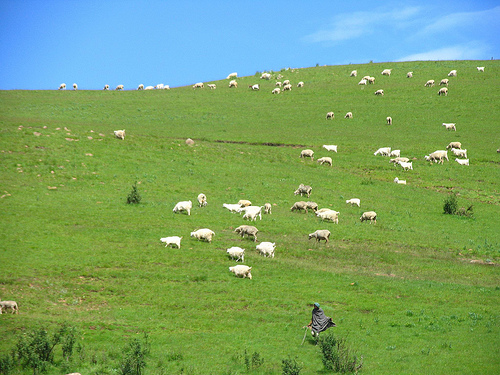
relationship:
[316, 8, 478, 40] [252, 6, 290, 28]
clouds in sky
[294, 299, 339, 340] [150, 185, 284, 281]
person watching sheep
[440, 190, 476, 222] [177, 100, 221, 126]
bush on hill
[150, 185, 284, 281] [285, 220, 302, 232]
sheep eating grass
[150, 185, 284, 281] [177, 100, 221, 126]
sheep on top of hill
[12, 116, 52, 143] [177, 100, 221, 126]
rocks on top of hill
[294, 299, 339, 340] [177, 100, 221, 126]
man on top of hill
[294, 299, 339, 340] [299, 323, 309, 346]
man has a cane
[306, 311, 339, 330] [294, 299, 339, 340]
coverall around man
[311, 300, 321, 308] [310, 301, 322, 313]
cap on top of head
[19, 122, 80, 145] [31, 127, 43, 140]
patches of dirt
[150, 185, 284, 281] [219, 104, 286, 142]
sheep on top of a field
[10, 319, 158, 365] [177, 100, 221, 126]
shrubs on top of hill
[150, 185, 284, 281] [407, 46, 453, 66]
sheep on hillside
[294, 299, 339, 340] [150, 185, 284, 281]
man with sheep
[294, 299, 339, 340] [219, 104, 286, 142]
person on top of field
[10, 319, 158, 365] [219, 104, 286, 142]
trees on top of field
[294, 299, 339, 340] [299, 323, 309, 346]
person has a cane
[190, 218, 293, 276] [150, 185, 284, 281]
sheep in herd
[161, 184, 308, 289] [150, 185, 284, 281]
sheep in group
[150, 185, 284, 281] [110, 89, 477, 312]
flock in field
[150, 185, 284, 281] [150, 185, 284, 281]
sheep in group